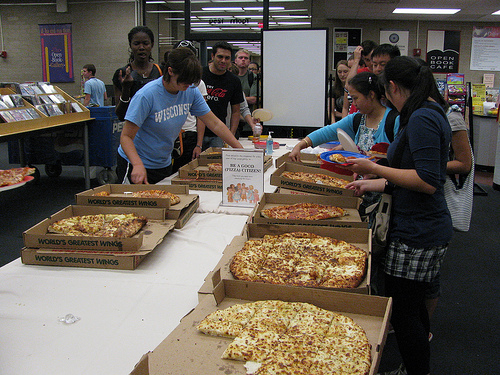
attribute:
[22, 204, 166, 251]
box — opened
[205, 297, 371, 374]
pizza — sliced, cheese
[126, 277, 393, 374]
box — greasy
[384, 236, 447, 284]
skirt — plaid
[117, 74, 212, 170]
shirt — blue, light blue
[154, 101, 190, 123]
lettering — white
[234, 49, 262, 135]
person — waiting, looking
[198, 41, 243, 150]
person — waiting, looking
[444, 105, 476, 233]
purse — white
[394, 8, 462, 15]
light — overhead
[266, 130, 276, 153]
hand sanitizer — sitting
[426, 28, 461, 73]
sign — open book cafe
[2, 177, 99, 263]
carpet — grey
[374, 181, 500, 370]
carpet — grey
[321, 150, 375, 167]
dish — blue, paper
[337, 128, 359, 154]
plate — white, thin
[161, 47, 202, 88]
hair — brown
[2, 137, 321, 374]
table — white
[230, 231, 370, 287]
pizza — large, boxed, cheese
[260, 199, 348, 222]
pizza — pepperoni, large